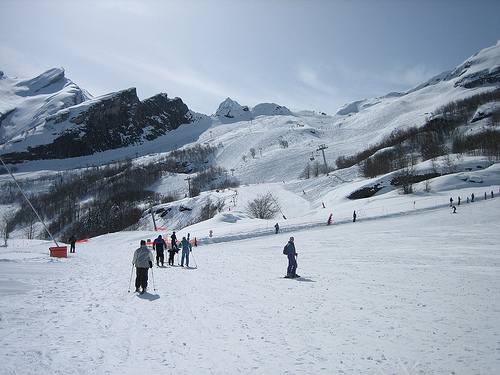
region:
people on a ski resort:
[62, 174, 498, 315]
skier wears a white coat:
[121, 236, 159, 301]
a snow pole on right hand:
[145, 255, 160, 295]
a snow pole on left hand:
[124, 260, 136, 295]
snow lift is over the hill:
[265, 140, 338, 176]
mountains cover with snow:
[0, 38, 497, 168]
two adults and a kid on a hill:
[153, 230, 198, 270]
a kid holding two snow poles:
[163, 238, 183, 269]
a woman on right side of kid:
[167, 233, 199, 269]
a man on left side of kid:
[151, 231, 178, 267]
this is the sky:
[225, 14, 410, 63]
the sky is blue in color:
[283, 9, 425, 46]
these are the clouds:
[185, 72, 367, 99]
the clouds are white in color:
[283, 84, 360, 104]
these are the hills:
[18, 75, 498, 142]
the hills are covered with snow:
[6, 81, 26, 111]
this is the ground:
[184, 282, 319, 368]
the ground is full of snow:
[180, 277, 264, 335]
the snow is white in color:
[186, 320, 256, 367]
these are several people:
[113, 235, 318, 293]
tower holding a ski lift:
[314, 141, 335, 179]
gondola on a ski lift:
[307, 153, 317, 164]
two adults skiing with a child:
[150, 233, 200, 270]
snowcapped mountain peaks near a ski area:
[29, 63, 208, 153]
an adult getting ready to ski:
[123, 237, 163, 303]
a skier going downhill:
[450, 203, 459, 218]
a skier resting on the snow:
[272, 236, 310, 281]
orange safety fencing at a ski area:
[143, 233, 175, 253]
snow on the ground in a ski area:
[336, 235, 468, 331]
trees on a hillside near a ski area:
[378, 98, 499, 167]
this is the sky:
[241, 22, 393, 58]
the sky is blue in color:
[359, 16, 460, 51]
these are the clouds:
[290, 60, 330, 82]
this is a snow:
[240, 124, 292, 169]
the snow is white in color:
[351, 252, 431, 335]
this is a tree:
[103, 187, 117, 219]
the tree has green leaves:
[108, 197, 122, 222]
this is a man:
[135, 232, 155, 291]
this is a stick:
[148, 270, 159, 301]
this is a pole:
[318, 135, 332, 171]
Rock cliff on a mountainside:
[107, 85, 184, 135]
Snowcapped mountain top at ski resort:
[21, 66, 87, 101]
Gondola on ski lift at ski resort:
[307, 151, 317, 162]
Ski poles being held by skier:
[125, 258, 134, 295]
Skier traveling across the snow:
[279, 227, 306, 285]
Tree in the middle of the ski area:
[247, 193, 277, 220]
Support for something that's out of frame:
[0, 148, 68, 258]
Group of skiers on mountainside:
[153, 227, 199, 273]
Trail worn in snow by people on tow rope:
[232, 188, 499, 245]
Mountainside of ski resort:
[132, 83, 489, 373]